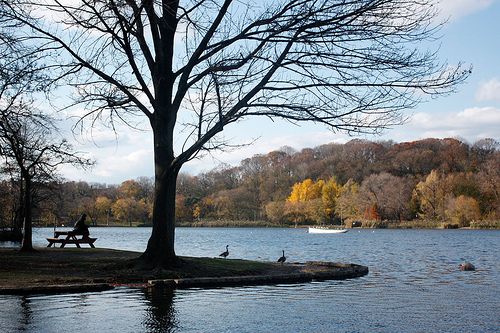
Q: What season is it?
A: Fall.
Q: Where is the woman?
A: On the picnic bench.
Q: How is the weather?
A: Partly cloudy.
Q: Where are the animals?
A: Next to the lake.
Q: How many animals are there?
A: Two.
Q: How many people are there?
A: One.